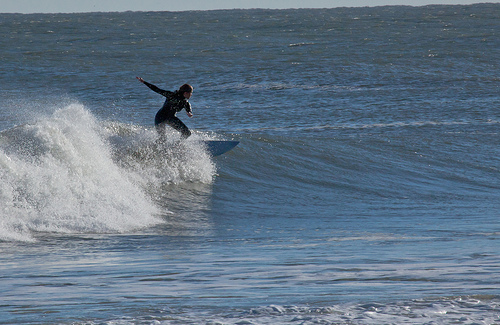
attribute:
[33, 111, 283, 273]
ripples — small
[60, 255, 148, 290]
ripples — small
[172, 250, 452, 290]
ripples — small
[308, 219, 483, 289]
ripples — small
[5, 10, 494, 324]
water — wavy, body, blue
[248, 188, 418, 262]
ripples — small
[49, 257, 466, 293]
ripples — small